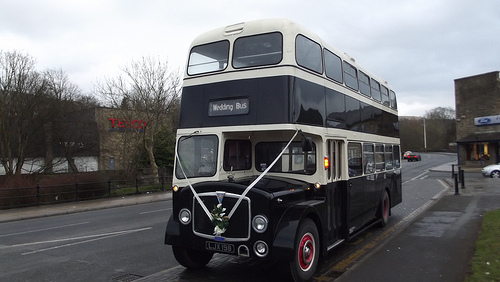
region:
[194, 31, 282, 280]
A bus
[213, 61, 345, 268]
A bus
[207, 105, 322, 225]
A bus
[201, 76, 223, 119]
A bus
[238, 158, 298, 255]
A bus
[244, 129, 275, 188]
A bus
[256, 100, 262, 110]
A bus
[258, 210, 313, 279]
A bus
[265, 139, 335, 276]
A bus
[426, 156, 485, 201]
black rail on the side of the road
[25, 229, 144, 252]
white lines running down the street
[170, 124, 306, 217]
white lines on the front of the bus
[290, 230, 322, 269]
red trim in the wheel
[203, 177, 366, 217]
black paint on the bus front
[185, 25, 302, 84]
large windows at top of bus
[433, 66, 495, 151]
tall brown building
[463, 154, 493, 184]
edge of white car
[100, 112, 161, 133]
large red sign on building front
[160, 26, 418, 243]
large black double decker bus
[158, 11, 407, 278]
double decker wedding bus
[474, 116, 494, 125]
blue logo on a sign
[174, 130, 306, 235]
white ribbon and flowers on the front of a bus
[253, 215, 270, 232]
white headlights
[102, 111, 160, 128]
red text hidden by a tree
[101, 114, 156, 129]
red text on a building reading Texco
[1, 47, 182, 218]
bunch of trees without leaves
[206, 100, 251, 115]
white text reading Wedding Bus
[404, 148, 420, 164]
black car on a road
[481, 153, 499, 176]
white vehicle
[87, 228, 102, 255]
the line is white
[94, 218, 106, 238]
the line is white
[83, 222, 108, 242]
the line is white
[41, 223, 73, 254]
the line is white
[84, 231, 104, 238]
the line is white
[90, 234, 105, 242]
the line is white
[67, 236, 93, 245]
the line is white